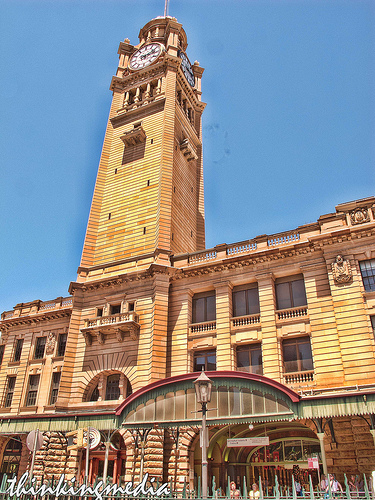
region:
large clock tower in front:
[20, 19, 204, 313]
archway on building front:
[33, 353, 308, 465]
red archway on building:
[83, 360, 302, 450]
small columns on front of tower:
[94, 70, 182, 118]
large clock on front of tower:
[131, 30, 169, 68]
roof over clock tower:
[107, 7, 197, 50]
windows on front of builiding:
[137, 271, 322, 370]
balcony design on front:
[158, 297, 325, 350]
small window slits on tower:
[142, 167, 167, 189]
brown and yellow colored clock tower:
[0, 121, 178, 259]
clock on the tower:
[131, 34, 169, 64]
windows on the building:
[180, 321, 307, 376]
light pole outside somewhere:
[180, 369, 219, 409]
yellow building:
[327, 311, 359, 356]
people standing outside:
[215, 471, 263, 494]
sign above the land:
[210, 420, 279, 454]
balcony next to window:
[71, 301, 141, 343]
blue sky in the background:
[11, 180, 65, 225]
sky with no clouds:
[231, 64, 332, 139]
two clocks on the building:
[127, 30, 213, 96]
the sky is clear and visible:
[225, 46, 292, 174]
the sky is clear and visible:
[221, 44, 370, 228]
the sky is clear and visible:
[229, 126, 337, 232]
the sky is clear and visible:
[233, 27, 336, 175]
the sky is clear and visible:
[227, 105, 290, 167]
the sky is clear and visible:
[209, 91, 329, 179]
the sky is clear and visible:
[263, 71, 343, 264]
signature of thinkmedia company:
[5, 471, 177, 497]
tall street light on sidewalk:
[188, 358, 220, 497]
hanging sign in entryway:
[222, 422, 280, 450]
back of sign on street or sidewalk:
[22, 424, 47, 490]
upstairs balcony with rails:
[75, 300, 144, 343]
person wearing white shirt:
[324, 466, 343, 496]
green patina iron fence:
[210, 472, 373, 494]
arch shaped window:
[72, 361, 135, 403]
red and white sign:
[303, 451, 321, 471]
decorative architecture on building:
[326, 249, 353, 286]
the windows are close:
[128, 219, 320, 377]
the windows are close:
[198, 261, 337, 387]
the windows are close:
[138, 215, 346, 491]